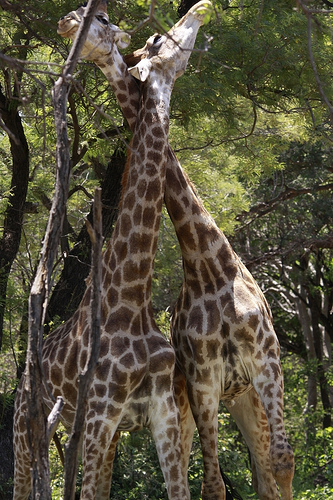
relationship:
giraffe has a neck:
[45, 1, 217, 499] [98, 82, 174, 322]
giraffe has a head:
[45, 1, 217, 499] [126, 1, 213, 79]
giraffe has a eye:
[45, 1, 217, 499] [153, 31, 164, 45]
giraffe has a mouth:
[45, 1, 217, 499] [178, 1, 215, 33]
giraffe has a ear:
[45, 1, 217, 499] [128, 59, 154, 81]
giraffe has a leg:
[45, 1, 217, 499] [250, 360, 295, 500]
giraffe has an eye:
[45, 1, 217, 499] [153, 31, 164, 45]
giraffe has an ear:
[45, 1, 217, 499] [128, 59, 154, 81]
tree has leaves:
[171, 3, 332, 162] [183, 10, 310, 120]